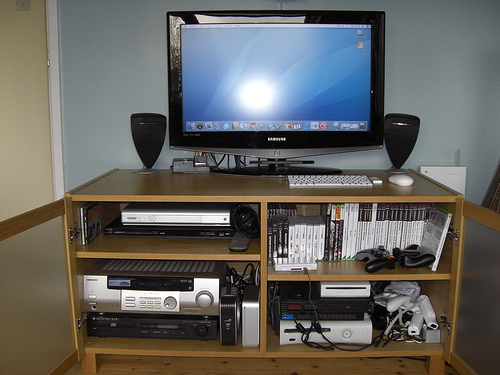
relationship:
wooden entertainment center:
[128, 175, 207, 198] [77, 198, 457, 369]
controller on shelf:
[359, 247, 394, 270] [265, 200, 452, 273]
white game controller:
[276, 257, 315, 271] [359, 247, 394, 270]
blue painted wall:
[82, 38, 141, 87] [398, 11, 479, 107]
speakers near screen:
[382, 112, 421, 169] [172, 11, 385, 142]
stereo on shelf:
[83, 262, 217, 310] [265, 200, 452, 273]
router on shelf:
[221, 288, 238, 348] [265, 200, 452, 273]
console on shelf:
[279, 322, 372, 346] [265, 200, 452, 273]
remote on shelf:
[231, 232, 252, 249] [265, 200, 452, 273]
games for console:
[326, 205, 358, 260] [279, 322, 372, 346]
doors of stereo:
[0, 224, 70, 374] [83, 262, 217, 310]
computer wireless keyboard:
[172, 11, 385, 142] [288, 176, 370, 188]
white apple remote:
[371, 173, 383, 187] [231, 232, 252, 249]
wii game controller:
[419, 295, 436, 332] [359, 247, 394, 270]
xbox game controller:
[279, 322, 372, 346] [359, 247, 394, 270]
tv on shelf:
[172, 11, 385, 142] [265, 200, 452, 273]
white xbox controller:
[371, 173, 383, 187] [359, 247, 394, 270]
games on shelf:
[326, 205, 358, 260] [265, 200, 452, 273]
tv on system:
[172, 11, 385, 142] [77, 198, 457, 369]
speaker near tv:
[131, 114, 169, 171] [172, 11, 385, 142]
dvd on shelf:
[122, 208, 228, 226] [265, 200, 452, 273]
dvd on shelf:
[80, 203, 102, 245] [67, 201, 264, 255]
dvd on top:
[122, 208, 228, 226] [67, 201, 264, 255]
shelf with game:
[265, 200, 452, 273] [273, 212, 444, 267]